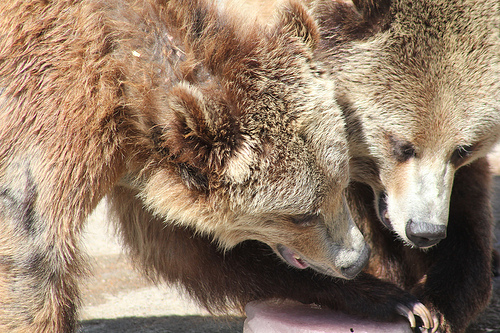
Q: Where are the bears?
A: In a park.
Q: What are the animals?
A: Bears.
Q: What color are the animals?
A: Brown.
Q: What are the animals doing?
A: Playing.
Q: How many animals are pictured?
A: Two.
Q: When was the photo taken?
A: Daytime.